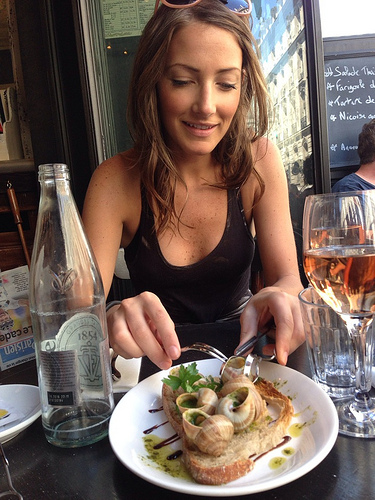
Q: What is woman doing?
A: Eating.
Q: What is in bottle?
A: Nothing it's empty.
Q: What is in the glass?
A: Wine.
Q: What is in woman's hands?
A: Utensils.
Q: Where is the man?
A: To right in back.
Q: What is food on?
A: White plate.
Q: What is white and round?
A: Plate.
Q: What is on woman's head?
A: Glasses.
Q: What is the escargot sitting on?
A: Toast.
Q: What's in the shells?
A: Escargot.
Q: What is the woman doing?
A: Eating shellfish.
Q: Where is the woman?
A: A restaurant.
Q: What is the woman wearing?
A: A tank top.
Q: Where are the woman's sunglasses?
A: On her head.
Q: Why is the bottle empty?
A: She poured it in her glass.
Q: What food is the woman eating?
A: Escargot.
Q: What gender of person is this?
A: Female.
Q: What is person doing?
A: Eating.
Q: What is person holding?
A: Silverware.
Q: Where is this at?
A: Restaurant.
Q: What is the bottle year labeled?
A: 1854.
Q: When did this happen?
A: During the day time.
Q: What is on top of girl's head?
A: Sunglasses.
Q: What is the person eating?
A: An Italian dish.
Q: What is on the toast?
A: Shells.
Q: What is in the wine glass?
A: Peach beverage.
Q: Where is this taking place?
A: In a restaurant.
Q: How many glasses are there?
A: Two.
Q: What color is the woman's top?
A: Black.